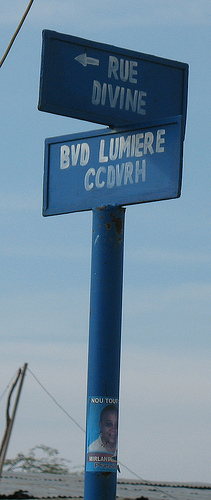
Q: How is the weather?
A: It is clear.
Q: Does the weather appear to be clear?
A: Yes, it is clear.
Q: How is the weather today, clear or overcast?
A: It is clear.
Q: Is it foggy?
A: No, it is clear.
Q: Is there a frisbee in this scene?
A: No, there are no frisbees.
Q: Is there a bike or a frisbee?
A: No, there are no frisbees or bikes.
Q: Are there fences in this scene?
A: No, there are no fences.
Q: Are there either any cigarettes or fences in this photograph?
A: No, there are no fences or cigarettes.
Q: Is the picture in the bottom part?
A: Yes, the picture is in the bottom of the image.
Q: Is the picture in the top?
A: No, the picture is in the bottom of the image.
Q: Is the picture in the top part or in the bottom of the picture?
A: The picture is in the bottom of the image.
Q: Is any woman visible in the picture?
A: Yes, there is a woman.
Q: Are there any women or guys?
A: Yes, there is a woman.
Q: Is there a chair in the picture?
A: No, there are no chairs.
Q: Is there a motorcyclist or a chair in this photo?
A: No, there are no chairs or bikers.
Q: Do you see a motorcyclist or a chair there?
A: No, there are no chairs or bikers.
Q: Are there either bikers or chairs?
A: No, there are no chairs or bikers.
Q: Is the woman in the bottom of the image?
A: Yes, the woman is in the bottom of the image.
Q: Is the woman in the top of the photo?
A: No, the woman is in the bottom of the image.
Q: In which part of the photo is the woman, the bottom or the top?
A: The woman is in the bottom of the image.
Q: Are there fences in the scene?
A: No, there are no fences.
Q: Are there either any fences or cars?
A: No, there are no fences or cars.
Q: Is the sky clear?
A: Yes, the sky is clear.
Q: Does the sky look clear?
A: Yes, the sky is clear.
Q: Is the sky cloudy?
A: No, the sky is clear.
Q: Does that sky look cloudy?
A: No, the sky is clear.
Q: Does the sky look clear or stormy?
A: The sky is clear.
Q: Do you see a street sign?
A: Yes, there is a street sign.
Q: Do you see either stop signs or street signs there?
A: Yes, there is a street sign.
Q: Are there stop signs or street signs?
A: Yes, there is a street sign.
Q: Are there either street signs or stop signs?
A: Yes, there is a street sign.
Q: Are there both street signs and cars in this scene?
A: No, there is a street sign but no cars.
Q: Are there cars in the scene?
A: No, there are no cars.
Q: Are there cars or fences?
A: No, there are no cars or fences.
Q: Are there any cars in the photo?
A: No, there are no cars.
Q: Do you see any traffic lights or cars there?
A: No, there are no cars or traffic lights.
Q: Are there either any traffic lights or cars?
A: No, there are no cars or traffic lights.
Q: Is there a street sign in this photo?
A: Yes, there is a street sign.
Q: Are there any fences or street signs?
A: Yes, there is a street sign.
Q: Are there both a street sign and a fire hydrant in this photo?
A: No, there is a street sign but no fire hydrants.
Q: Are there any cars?
A: No, there are no cars.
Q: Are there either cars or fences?
A: No, there are no cars or fences.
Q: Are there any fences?
A: No, there are no fences.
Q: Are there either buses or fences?
A: No, there are no fences or buses.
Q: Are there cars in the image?
A: No, there are no cars.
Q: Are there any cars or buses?
A: No, there are no cars or buses.